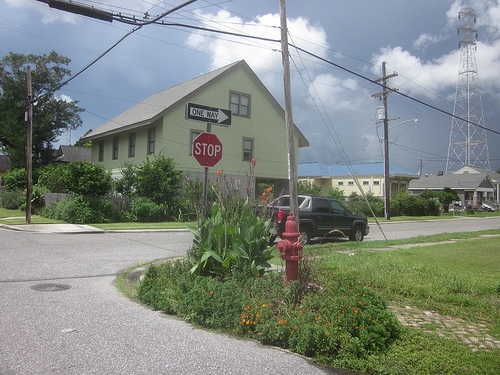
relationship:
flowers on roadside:
[235, 300, 362, 341] [82, 250, 212, 368]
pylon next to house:
[446, 5, 496, 185] [75, 53, 305, 209]